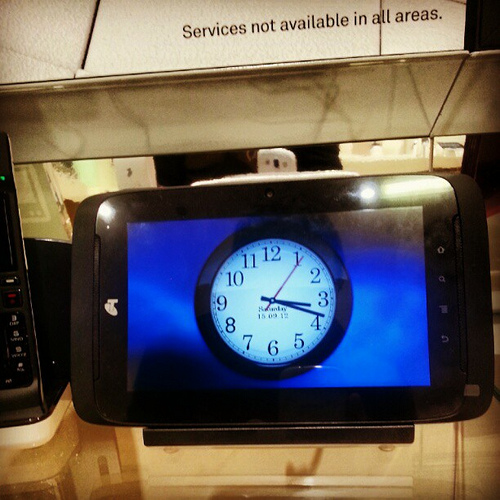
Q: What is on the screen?
A: A cell phone.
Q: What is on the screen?
A: A clock.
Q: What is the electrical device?
A: A phone.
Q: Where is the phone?
A: On display.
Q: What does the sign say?
A: Services not available in all areas.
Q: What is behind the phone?
A: A sign.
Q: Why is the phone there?
A: To display.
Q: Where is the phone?
A: At a retailer.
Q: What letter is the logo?
A: T.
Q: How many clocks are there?
A: One.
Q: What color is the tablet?
A: Black.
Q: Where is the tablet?
A: The table.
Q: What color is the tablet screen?
A: Blue.